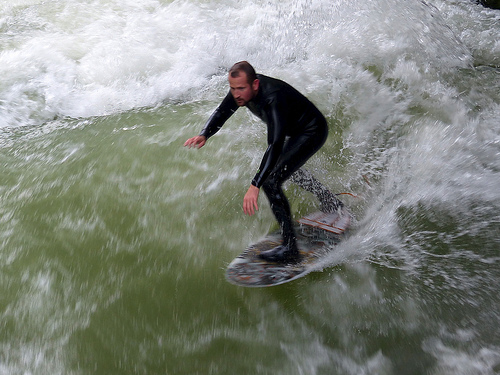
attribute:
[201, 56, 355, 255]
man — surfing, white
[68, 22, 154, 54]
water — green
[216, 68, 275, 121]
surfers face — concetrated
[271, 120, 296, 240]
wetsuit — black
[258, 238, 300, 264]
shoes — black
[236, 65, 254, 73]
hair — brown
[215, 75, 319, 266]
person — surfing